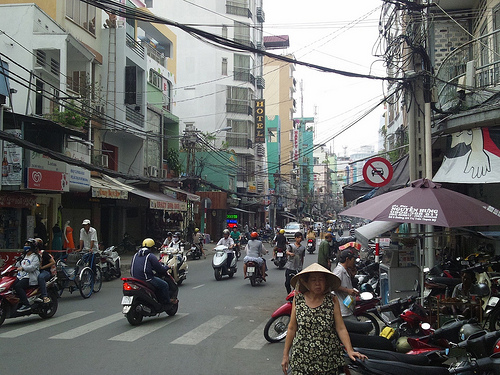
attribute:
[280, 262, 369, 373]
person — out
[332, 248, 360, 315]
person — out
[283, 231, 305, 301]
person — out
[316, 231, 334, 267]
person — out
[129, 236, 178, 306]
person — out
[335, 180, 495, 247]
umbrella — purple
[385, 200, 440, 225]
letters — white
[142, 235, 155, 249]
helmet — Yellow 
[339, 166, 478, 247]
umbrella — black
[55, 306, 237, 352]
cross walk — for pedestrians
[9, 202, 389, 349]
people — shopping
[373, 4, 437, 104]
tangle — wire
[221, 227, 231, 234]
helmet — white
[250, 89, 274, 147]
sign — black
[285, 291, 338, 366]
dress — black, flowered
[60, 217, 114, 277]
dress — orange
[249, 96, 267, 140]
hotel — yellow